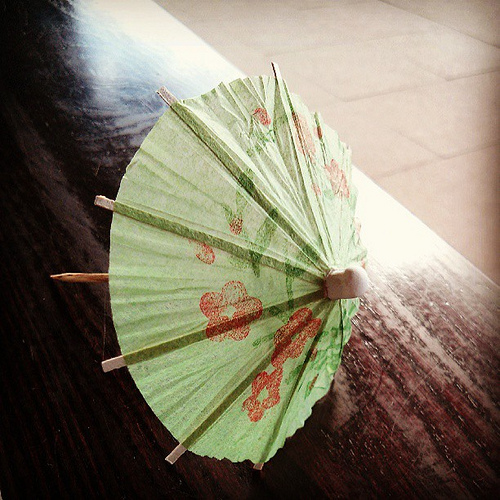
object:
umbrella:
[49, 60, 368, 470]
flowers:
[197, 279, 264, 342]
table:
[0, 0, 499, 500]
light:
[83, 0, 500, 291]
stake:
[49, 271, 109, 283]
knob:
[325, 264, 368, 302]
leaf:
[245, 206, 283, 281]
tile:
[352, 78, 499, 158]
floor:
[149, 0, 499, 288]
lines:
[0, 378, 92, 497]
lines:
[261, 2, 499, 168]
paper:
[108, 74, 368, 464]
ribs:
[100, 286, 334, 374]